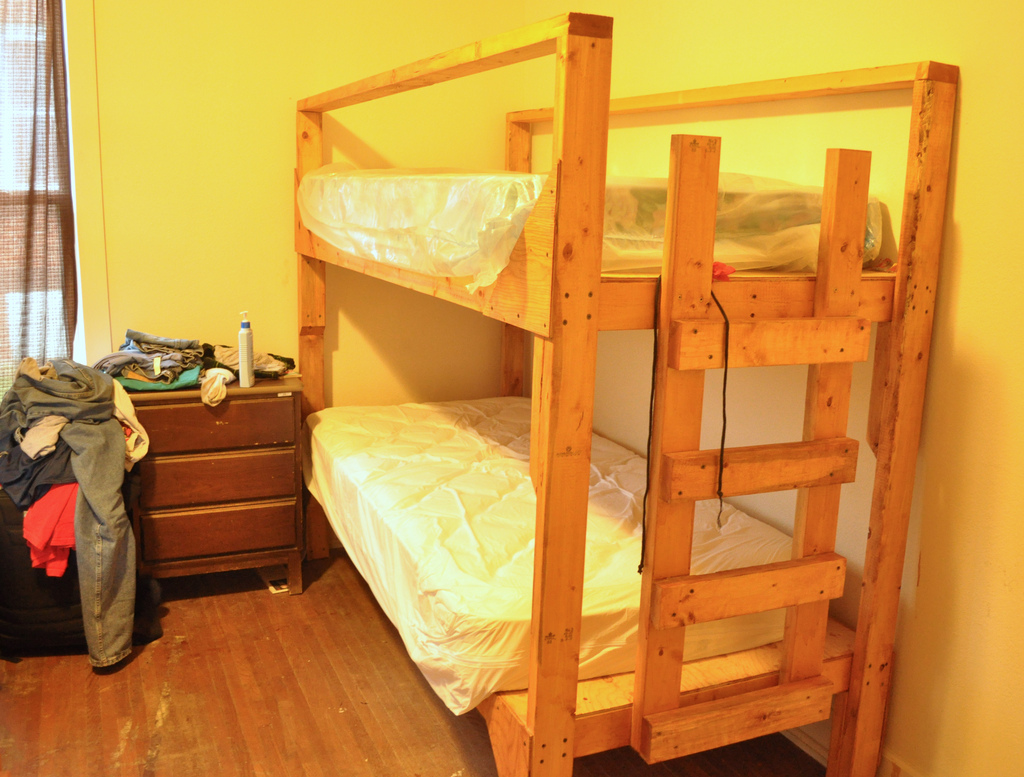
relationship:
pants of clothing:
[0, 357, 137, 668] [14, 376, 170, 679]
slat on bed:
[664, 547, 861, 640] [297, 11, 967, 774]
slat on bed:
[291, 113, 337, 395] [297, 11, 967, 774]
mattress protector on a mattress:
[415, 627, 552, 705] [287, 337, 838, 720]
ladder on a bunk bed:
[667, 253, 916, 705] [265, 18, 905, 766]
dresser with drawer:
[121, 379, 336, 619] [114, 407, 311, 464]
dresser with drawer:
[121, 379, 336, 619] [142, 497, 322, 586]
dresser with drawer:
[121, 379, 336, 619] [136, 441, 303, 526]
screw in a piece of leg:
[549, 281, 586, 308] [525, 12, 608, 775]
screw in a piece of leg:
[572, 279, 598, 314] [525, 12, 608, 775]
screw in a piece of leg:
[553, 309, 580, 346] [525, 12, 608, 775]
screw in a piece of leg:
[576, 307, 605, 340] [525, 12, 608, 775]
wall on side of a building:
[61, 0, 1024, 777] [36, 7, 950, 766]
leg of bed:
[510, 424, 649, 636] [283, 57, 979, 407]